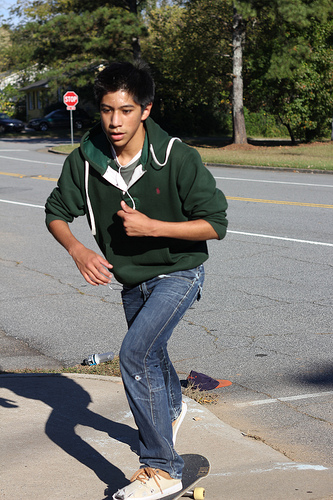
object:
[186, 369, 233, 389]
cap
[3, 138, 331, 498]
ground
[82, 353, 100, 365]
bottle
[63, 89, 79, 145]
sign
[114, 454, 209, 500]
skateboard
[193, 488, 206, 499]
wheels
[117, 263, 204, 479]
jeans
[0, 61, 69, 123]
house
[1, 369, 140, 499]
shadow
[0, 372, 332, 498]
sidewalk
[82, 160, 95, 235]
draw string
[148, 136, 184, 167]
draw string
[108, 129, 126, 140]
mouth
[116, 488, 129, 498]
hole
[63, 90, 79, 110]
stop sign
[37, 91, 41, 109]
shutter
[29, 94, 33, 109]
shutter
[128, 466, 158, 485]
laces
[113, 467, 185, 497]
shoe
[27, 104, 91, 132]
car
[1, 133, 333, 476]
driveway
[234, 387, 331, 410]
line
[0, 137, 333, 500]
pavement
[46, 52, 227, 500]
boy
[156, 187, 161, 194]
emblem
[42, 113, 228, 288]
hoodie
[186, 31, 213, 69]
greenery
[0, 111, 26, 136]
cars